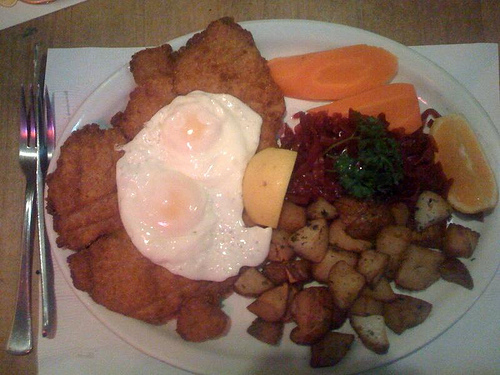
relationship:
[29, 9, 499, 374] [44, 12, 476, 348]
breakfast on plate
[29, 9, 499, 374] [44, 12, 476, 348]
food on plate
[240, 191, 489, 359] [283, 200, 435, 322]
spices on potatoes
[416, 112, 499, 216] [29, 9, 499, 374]
orange slice on plate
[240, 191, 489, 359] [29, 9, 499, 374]
potatoes on plate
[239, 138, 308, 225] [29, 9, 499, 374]
lemon on plate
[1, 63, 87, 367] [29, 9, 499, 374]
fork on plate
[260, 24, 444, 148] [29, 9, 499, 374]
carrots on plate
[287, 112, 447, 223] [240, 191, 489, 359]
salsa on potatoes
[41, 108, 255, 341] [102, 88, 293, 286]
chicken with eggs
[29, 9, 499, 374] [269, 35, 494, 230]
meal with veggies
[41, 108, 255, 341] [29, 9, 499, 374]
chicken on plate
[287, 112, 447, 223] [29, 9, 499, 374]
red relish on plate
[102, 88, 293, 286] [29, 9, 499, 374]
eggs on plate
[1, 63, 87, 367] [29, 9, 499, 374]
fork by a plate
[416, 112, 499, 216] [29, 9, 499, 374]
orange on plate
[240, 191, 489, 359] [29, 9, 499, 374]
potatos on plate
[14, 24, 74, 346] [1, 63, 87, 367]
knife and fork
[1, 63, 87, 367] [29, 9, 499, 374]
fork next to plate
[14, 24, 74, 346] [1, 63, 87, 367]
knife on top of fork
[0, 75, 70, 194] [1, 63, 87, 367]
tines on fork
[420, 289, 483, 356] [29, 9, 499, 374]
edge of plate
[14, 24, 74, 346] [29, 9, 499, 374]
knife beside plate